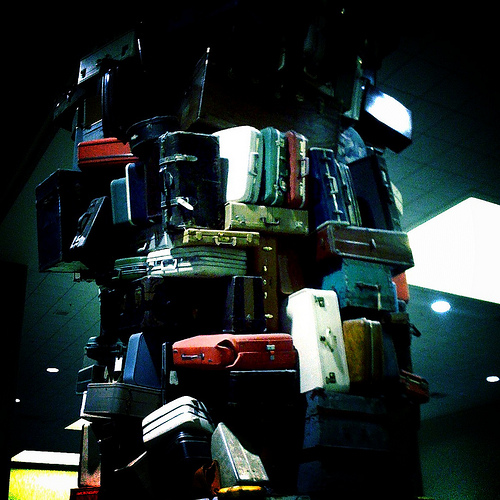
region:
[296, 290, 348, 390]
suitcase in the stack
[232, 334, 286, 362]
suitcase in the stack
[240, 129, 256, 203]
suitcase in the stack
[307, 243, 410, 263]
suitcase in the stack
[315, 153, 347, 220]
suitcase in the stack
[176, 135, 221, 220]
suitcase in the stack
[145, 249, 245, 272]
suitcase in the stack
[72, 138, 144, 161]
suitcase in the stack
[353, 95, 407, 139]
suitcase in the stack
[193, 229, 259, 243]
suitcase in the stack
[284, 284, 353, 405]
white suitcase in its side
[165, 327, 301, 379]
red suitcase in a pile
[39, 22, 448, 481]
tower of multi-colored suitcases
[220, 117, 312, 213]
trio of suitcases on their side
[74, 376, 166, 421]
blue suitcase in a pile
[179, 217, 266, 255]
yellowish briefcase in a large pile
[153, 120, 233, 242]
black trunk on its side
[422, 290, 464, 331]
circular recessed ceiling light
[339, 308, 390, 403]
mustard colored suitcase in a pile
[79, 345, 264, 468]
jumble of suitcases in a pile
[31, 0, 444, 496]
a large stack of suitcases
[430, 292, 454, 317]
a round light in the ceilng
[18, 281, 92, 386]
a white dropped tile ceiling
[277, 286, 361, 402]
a white suitcase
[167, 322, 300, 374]
a red suitcase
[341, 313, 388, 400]
a yellow suitcase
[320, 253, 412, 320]
a green trunk with a tag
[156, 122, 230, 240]
a black suitcase strapped shut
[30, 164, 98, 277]
a black trunk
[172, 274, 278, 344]
a black suitcase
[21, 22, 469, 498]
A large stack of suitcases.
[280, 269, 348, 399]
A white suitcase in a stack.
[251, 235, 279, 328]
Brown suitcase in a stack.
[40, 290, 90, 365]
Tiles on the ceiling.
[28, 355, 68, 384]
Small lights on the ceiling.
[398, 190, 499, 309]
A large square light.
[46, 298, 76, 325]
Vents on the ceiling.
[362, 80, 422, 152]
Light shining on a suitcase.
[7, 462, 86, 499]
The background is yellow.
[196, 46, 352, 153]
A large wooden trunk.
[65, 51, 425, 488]
The luggage is stacked.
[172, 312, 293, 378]
The suitcase is red.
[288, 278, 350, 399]
The suitcase is white.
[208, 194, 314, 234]
The suitcase is tan.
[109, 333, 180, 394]
The luggage is blue.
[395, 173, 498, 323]
The light is on.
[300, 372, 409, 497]
The luggage is black.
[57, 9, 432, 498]
This is a pile of luggage.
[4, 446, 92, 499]
This is the door outside.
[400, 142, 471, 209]
The ceiling is tiled.